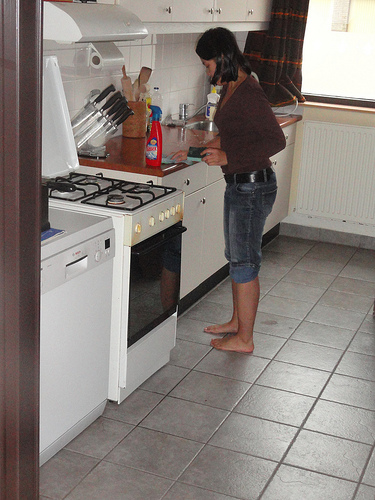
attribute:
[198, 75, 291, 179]
shirt — brown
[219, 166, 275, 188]
belt — black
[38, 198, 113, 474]
dishwasher — white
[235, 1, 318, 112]
curtain — brown, dark, heavy, open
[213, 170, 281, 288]
jeans — blue, dark blue, knee-length, capris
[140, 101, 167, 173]
cleaner — red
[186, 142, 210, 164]
sponge — green, light green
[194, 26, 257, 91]
hair — black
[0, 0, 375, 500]
kitchen — clean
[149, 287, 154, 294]
black oven — invisible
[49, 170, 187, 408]
oven — white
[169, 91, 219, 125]
faucet — silver metal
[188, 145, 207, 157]
scrubber — dark green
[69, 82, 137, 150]
knives — set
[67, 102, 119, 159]
holder — clear [i think]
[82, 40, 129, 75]
paper towel holder — white, mounted to wall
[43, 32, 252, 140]
kitchen wall — tiled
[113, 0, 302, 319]
cabinets — white, split, top+bottom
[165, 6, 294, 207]
knobs — silvertone, roundish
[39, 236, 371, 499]
floor — tiled floor, linoleum, marbled grey, tiled, square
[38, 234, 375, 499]
floor tiles — grey marbled, bland, large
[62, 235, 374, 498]
grey grout — the line maker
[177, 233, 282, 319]
white edge — also illusory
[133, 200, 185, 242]
dials — white, slightly discoloured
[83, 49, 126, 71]
paper towels — white, in a roll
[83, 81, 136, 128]
handles — black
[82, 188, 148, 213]
burner — black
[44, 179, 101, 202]
burner — black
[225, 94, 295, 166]
sleeves — long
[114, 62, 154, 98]
cooking utensils — wooden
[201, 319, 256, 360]
feet — bare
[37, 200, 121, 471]
washing machine — likely 'dishwasher'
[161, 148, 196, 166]
rag — bluish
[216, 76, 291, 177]
sweater — brown, reddish maybe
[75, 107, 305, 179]
countertop — reddish orange, brown